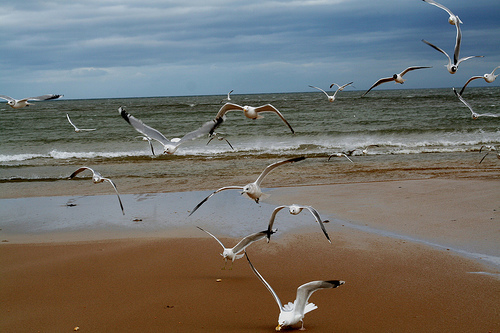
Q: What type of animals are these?
A: Birds.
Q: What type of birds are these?
A: Seagulls.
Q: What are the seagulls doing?
A: Flying.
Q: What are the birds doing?
A: Flying.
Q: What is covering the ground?
A: Sand.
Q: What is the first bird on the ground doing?
A: Eating.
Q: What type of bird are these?
A: Seagulls.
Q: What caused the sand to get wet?
A: Water.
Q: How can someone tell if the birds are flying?
A: Wings are spread in air.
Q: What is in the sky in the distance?
A: Clouds.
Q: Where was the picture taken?
A: Beach.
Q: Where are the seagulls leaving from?
A: Coast.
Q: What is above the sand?
A: Birds.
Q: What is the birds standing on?
A: Brown sand.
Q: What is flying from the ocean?
A: Birds.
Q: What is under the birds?
A: Shore.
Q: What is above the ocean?
A: Cloudy sky.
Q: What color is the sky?
A: Blue.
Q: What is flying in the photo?
A: Seaguls.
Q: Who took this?
A: A tourists.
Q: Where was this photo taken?
A: The beach.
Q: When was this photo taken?
A: In the afternoon.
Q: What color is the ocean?
A: Gray.